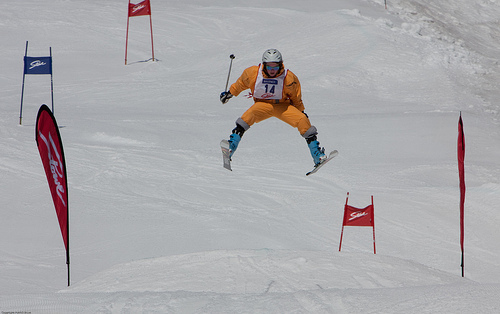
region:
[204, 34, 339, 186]
a skier in the air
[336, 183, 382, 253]
a red marker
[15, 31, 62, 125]
a blue marker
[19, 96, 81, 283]
a red flag in the snow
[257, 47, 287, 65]
a white helmet on the skier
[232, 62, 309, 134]
the skier is wearing yellow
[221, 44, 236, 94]
the ski pole is behind him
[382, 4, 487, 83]
snow piles on the side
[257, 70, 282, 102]
he is wearing a white bib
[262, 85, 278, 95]
the number 14 on the bib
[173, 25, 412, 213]
a skier in the air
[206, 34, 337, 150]
yellow uniform on skier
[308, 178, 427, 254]
a red banner between two red sticks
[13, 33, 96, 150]
a blue banner between two blue sticks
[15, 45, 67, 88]
a blue and white banner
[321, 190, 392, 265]
a red and white banner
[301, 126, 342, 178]
blue and black boots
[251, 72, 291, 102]
number 14 on chest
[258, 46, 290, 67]
white helmet on head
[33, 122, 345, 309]
lines in the snow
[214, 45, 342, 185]
skier wearing an orange ski suit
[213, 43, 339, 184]
skier in mid air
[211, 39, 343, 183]
skier wearing blue ski boots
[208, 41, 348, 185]
skier wearing the number 14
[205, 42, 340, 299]
skier jumping over snow hill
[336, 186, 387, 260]
red ski flag in white snow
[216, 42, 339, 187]
skier is wearing a gray helmet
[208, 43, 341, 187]
skier weaing gray skis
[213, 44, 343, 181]
a person skiing in an orange ski suit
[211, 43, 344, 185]
skier wearing ski goggles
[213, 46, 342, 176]
Snowboarder is airborne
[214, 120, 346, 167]
Snowboarder is wearing blue ski shoes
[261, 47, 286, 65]
Snowboarder's helmet is gray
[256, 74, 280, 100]
Snowboarder's number is 14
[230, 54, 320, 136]
Snowboarder is wearing a yellow ski suit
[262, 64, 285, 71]
Snowboarder wearing blue glasses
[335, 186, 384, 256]
Short mark in snow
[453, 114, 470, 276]
Long skinny mark in snow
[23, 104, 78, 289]
Long flat mark in snow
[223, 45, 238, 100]
Snowboarder holding one guide